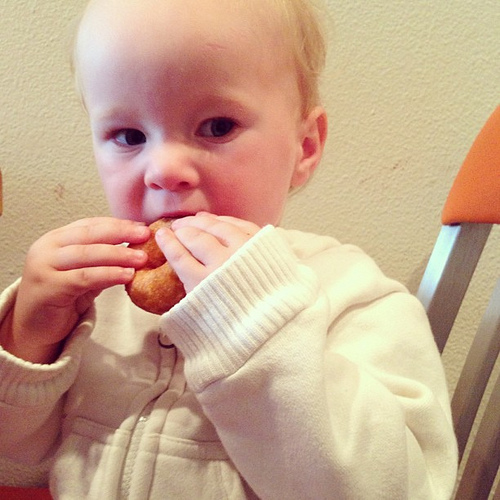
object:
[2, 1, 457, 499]
baby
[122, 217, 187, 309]
donut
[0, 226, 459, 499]
sweater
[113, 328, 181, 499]
zipper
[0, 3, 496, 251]
wall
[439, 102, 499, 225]
stuff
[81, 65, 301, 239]
face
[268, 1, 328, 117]
hair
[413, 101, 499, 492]
chair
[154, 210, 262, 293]
hand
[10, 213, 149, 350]
hand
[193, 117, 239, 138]
eye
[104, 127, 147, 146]
eye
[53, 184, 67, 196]
food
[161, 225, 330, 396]
cuff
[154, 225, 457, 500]
sleeve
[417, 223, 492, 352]
bar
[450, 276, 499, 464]
bar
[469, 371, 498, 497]
bar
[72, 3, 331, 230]
head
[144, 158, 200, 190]
nose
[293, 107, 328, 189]
ear